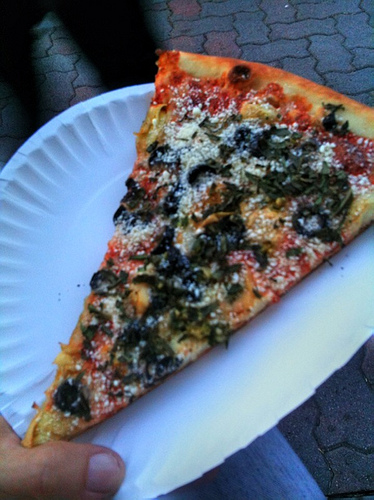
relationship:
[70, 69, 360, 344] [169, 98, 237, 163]
pizza has cheese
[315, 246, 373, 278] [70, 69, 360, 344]
crumbs of pizza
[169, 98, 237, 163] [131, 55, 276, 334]
cheese on slice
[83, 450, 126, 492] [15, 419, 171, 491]
nail on thumb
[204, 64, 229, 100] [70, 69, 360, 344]
sauce on pizza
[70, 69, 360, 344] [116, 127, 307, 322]
pizza has toppings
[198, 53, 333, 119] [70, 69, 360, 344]
crust of pizza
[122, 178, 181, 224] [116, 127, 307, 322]
olives as toppings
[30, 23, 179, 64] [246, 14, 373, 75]
shadows on bricks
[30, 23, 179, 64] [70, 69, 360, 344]
shadows of pizza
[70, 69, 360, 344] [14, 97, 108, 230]
pizza on plate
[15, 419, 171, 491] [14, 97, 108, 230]
thumb on plate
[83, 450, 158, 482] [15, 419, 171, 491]
nail on thumb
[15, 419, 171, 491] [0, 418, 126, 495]
thumb on hand